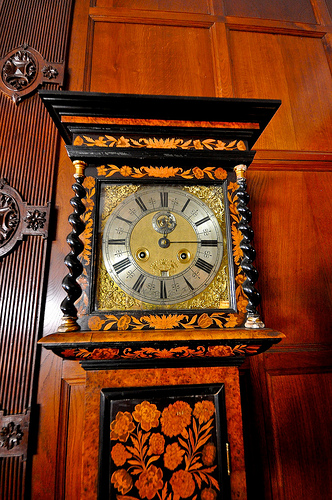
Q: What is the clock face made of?
A: Metal.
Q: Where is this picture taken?
A: A living room.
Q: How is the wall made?
A: Of wood paneling.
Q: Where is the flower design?
A: On clock.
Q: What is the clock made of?
A: Wood.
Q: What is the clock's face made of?
A: Gold and silver.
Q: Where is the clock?
A: Beside wall.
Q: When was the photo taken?
A: 12.15.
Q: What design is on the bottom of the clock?
A: A floral motif.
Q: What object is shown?
A: A clock.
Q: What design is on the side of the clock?
A: A twisted decoration.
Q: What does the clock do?
A: Tell time.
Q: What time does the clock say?
A: 12:15.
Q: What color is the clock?
A: Brown, black, gold and silver.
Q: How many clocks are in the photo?
A: One.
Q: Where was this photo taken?
A: In a wood lined room.